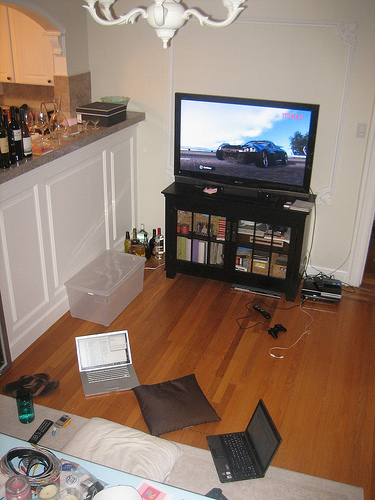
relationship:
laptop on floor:
[74, 329, 140, 397] [0, 239, 373, 498]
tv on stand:
[173, 91, 321, 194] [161, 178, 317, 304]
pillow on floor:
[129, 376, 227, 444] [0, 239, 373, 498]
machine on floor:
[230, 272, 350, 371] [0, 239, 373, 498]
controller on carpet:
[13, 388, 38, 429] [0, 390, 95, 459]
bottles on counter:
[3, 108, 56, 161] [0, 108, 147, 180]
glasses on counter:
[27, 121, 47, 139] [0, 108, 147, 180]